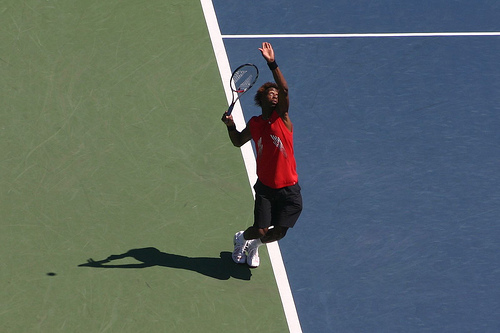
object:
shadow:
[78, 246, 253, 280]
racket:
[223, 63, 259, 124]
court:
[0, 0, 500, 333]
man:
[219, 41, 302, 268]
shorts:
[242, 172, 310, 234]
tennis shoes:
[247, 239, 260, 267]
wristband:
[267, 59, 279, 70]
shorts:
[253, 178, 303, 228]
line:
[197, 0, 305, 333]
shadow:
[46, 271, 57, 276]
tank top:
[247, 109, 299, 189]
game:
[0, 0, 500, 333]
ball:
[46, 272, 57, 277]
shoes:
[232, 230, 248, 264]